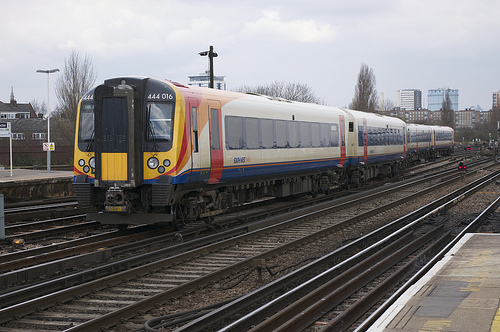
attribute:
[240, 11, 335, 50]
clouds — white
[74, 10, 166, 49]
clouds — white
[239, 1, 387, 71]
clouds — white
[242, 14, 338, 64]
clouds — white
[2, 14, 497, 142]
sky — blue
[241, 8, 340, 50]
clouds — white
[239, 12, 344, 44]
cloud — white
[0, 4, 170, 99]
cloud — white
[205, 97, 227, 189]
door — red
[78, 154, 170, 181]
lights —  six,  train's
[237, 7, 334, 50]
cloud — white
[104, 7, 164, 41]
cloud — white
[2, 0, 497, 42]
sky — blue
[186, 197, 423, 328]
tracks — silver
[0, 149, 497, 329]
tracks —  train's,  of railway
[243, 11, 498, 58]
clouds — white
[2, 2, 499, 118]
sky — blue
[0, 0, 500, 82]
clouds — white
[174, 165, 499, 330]
tracks — rusty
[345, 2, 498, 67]
cloud — white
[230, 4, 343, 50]
cloud — white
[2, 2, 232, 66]
cloud — white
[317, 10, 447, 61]
clouds — white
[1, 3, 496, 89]
sky — blue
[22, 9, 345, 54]
clouds — white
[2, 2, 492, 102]
sky — blue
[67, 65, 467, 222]
train —  two,  of railway station, long, yellow, white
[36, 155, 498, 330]
tracks — metal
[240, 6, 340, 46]
cloud — white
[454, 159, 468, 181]
lights —  small,   red 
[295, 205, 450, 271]
tracks — metal, straight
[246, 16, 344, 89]
clouds — white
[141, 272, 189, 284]
sleeper — wooden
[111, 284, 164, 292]
sleeper — wooden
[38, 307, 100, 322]
sleeper — wooden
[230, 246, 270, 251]
sleeper — wooden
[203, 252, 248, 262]
sleeper — wooden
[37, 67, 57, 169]
pole — white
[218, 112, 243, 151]
windows —  some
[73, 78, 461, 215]
train — white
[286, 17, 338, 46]
clouds — white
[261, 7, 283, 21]
clouds — white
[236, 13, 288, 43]
clouds — white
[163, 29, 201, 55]
clouds — white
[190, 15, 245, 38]
clouds — white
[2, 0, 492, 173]
sky — blue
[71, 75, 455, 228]
white train — yellow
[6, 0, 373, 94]
cloud — white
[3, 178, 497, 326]
railway — wide